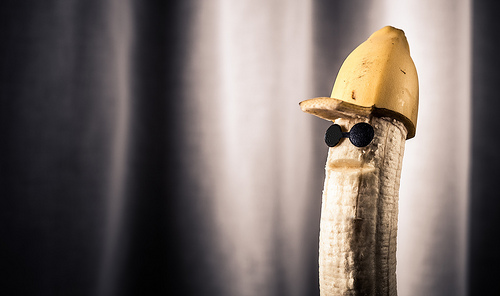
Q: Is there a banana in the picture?
A: Yes, there is a banana.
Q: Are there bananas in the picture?
A: Yes, there is a banana.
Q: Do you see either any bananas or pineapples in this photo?
A: Yes, there is a banana.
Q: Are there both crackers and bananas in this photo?
A: No, there is a banana but no crackers.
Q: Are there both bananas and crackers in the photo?
A: No, there is a banana but no crackers.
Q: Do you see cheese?
A: No, there is no cheese.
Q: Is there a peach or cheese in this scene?
A: No, there are no cheese or peaches.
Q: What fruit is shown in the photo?
A: The fruit is a banana.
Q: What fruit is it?
A: The fruit is a banana.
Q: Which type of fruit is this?
A: This is a banana.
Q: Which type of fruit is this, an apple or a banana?
A: This is a banana.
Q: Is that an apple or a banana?
A: That is a banana.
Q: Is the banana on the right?
A: Yes, the banana is on the right of the image.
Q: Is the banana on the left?
A: No, the banana is on the right of the image.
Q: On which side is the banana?
A: The banana is on the right of the image.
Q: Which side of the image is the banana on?
A: The banana is on the right of the image.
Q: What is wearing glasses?
A: The banana is wearing glasses.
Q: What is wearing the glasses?
A: The banana is wearing glasses.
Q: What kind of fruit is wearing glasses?
A: The fruit is a banana.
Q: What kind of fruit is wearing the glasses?
A: The fruit is a banana.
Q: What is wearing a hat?
A: The banana is wearing a hat.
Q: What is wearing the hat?
A: The banana is wearing a hat.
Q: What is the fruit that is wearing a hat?
A: The fruit is a banana.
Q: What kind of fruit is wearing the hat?
A: The fruit is a banana.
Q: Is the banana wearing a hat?
A: Yes, the banana is wearing a hat.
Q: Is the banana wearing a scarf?
A: No, the banana is wearing a hat.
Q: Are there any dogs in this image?
A: No, there are no dogs.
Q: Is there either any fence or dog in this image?
A: No, there are no dogs or fences.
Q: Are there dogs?
A: No, there are no dogs.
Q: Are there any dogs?
A: No, there are no dogs.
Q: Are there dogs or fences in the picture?
A: No, there are no dogs or fences.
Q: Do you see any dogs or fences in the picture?
A: No, there are no dogs or fences.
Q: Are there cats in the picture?
A: No, there are no cats.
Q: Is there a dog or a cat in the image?
A: No, there are no cats or dogs.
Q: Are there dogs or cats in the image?
A: No, there are no cats or dogs.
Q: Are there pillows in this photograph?
A: No, there are no pillows.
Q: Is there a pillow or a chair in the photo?
A: No, there are no pillows or chairs.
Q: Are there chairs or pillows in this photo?
A: No, there are no pillows or chairs.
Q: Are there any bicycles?
A: No, there are no bicycles.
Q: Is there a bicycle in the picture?
A: No, there are no bicycles.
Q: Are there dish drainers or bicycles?
A: No, there are no bicycles or dish drainers.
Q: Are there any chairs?
A: No, there are no chairs.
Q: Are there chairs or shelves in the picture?
A: No, there are no chairs or shelves.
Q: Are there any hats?
A: Yes, there is a hat.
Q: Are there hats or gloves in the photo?
A: Yes, there is a hat.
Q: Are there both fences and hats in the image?
A: No, there is a hat but no fences.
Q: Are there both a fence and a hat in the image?
A: No, there is a hat but no fences.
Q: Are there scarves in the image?
A: No, there are no scarves.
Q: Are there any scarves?
A: No, there are no scarves.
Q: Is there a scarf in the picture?
A: No, there are no scarves.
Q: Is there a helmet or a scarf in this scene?
A: No, there are no scarves or helmets.